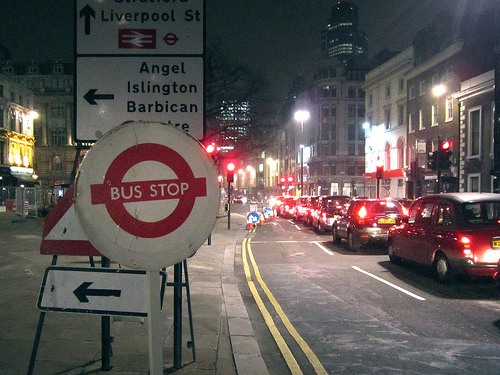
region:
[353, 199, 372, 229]
bright light on car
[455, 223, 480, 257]
bright light on car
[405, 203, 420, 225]
bright light on car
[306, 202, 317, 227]
bright light on car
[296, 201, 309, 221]
bright light on car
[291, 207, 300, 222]
bright light on car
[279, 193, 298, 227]
bright light on car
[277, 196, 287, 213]
bright light on car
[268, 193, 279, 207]
bright light on car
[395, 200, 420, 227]
bright light on car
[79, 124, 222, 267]
A sign for the bus stop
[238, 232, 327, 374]
Two yellow lines on the road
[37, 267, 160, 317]
A black arrow pointing to the left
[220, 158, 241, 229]
A red stop light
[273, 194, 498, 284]
Cars parked in a line on the road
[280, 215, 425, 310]
White lines on the road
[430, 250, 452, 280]
A wheel on a car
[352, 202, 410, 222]
Red lights on a car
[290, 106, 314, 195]
A street lamp by the road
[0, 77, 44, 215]
A building lit with lights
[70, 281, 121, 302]
a black arrow on the sign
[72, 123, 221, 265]
a white and red sign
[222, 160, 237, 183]
the street signal is red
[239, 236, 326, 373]
a double yellow line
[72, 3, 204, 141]
metal street sign with black text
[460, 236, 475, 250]
a red brake light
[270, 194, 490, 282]
traffic on the street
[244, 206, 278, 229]
row of orange cones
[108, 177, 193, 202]
sign says Bus Stop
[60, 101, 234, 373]
this is a sign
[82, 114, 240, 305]
red drawing on sign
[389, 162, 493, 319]
this is a car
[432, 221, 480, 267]
this is a breaklight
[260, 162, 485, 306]
road with cars on it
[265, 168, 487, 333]
the cars are stopped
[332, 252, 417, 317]
white line on the street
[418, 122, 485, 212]
this is a lit traffic light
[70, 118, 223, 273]
a circular bus stop sign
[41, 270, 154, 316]
a white street sign with an arrow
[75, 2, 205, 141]
street signs giving directions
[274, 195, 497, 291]
a long row of traffic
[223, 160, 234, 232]
a red street light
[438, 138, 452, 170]
a red street light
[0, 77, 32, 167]
a tall building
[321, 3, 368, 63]
the top of a tall skyscraper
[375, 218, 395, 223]
a yellow license plate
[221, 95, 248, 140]
a well lit building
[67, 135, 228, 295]
this is a sign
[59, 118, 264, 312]
the sign is red and white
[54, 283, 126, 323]
this is an arrow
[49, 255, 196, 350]
the arrow is black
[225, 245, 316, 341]
the lines are yellow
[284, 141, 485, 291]
the cars are stopped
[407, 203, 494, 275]
this car is red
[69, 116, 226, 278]
bus stop with red and white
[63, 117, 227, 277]
bus stop with red and white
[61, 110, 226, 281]
bus stop with red and white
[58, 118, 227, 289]
bus stop with red and white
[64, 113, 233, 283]
bus stop with red and white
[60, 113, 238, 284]
bus stop with red and white